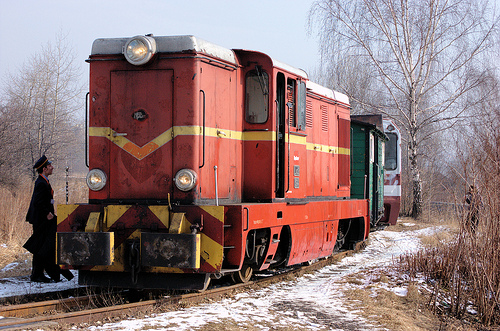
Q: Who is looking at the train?
A: The conductor.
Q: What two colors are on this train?
A: Yellow and red.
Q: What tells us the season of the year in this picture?
A: The snow on the ground.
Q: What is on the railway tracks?
A: The train.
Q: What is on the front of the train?
A: Lights.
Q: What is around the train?
A: Trees.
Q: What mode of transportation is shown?
A: Train.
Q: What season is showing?
A: Winter.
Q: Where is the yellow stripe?
A: Train engine.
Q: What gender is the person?
A: Male.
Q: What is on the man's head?
A: Hat.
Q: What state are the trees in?
A: Bare.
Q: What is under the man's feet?
A: Snow.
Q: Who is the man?
A: Conductor.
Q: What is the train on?
A: Tracks.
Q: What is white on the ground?
A: Snow.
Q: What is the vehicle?
A: Train.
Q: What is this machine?
A: A train.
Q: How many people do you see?
A: 1.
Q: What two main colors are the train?
A: Red and yellow.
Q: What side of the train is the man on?
A: The left side.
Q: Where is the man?
A: By the train.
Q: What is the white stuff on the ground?
A: Snow.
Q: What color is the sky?
A: Blue.